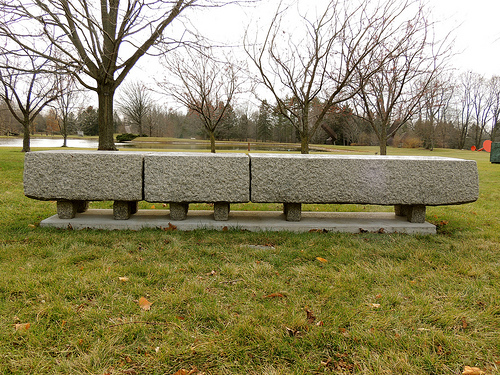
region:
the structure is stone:
[40, 142, 447, 194]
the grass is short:
[118, 296, 210, 370]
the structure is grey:
[287, 168, 346, 196]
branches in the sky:
[221, 28, 291, 70]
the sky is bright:
[197, 14, 234, 31]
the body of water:
[55, 135, 90, 150]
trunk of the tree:
[282, 89, 309, 152]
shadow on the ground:
[320, 207, 363, 220]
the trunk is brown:
[102, 100, 109, 130]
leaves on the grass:
[117, 280, 148, 322]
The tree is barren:
[46, 73, 83, 148]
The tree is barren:
[3, 52, 54, 147]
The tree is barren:
[51, 5, 140, 148]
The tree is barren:
[118, 83, 158, 139]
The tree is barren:
[153, 47, 239, 154]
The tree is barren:
[246, 22, 334, 152]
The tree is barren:
[346, 47, 422, 153]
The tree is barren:
[406, 78, 449, 149]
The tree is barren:
[446, 83, 480, 153]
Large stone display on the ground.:
[16, 140, 486, 230]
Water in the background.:
[0, 130, 327, 157]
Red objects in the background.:
[465, 133, 494, 158]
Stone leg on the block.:
[279, 201, 306, 222]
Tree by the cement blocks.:
[2, 0, 199, 155]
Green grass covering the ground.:
[2, 145, 499, 371]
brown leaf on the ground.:
[133, 292, 158, 314]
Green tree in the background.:
[77, 105, 103, 138]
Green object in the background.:
[486, 118, 498, 169]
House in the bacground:
[110, 102, 137, 138]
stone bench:
[17, 137, 489, 252]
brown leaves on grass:
[123, 267, 338, 347]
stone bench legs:
[48, 197, 428, 239]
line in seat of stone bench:
[128, 150, 160, 204]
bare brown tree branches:
[3, 3, 73, 80]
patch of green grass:
[43, 248, 89, 278]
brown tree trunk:
[88, 96, 128, 151]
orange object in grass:
[464, 131, 493, 154]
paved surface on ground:
[6, 130, 125, 152]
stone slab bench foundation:
[32, 205, 447, 243]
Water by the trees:
[2, 134, 122, 149]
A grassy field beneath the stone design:
[2, 145, 496, 374]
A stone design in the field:
[23, 151, 476, 236]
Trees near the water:
[0, 2, 496, 151]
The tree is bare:
[243, 1, 403, 155]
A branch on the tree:
[116, 0, 183, 87]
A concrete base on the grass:
[43, 211, 435, 230]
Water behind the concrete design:
[1, 137, 324, 154]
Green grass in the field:
[0, 147, 498, 373]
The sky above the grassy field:
[0, 0, 499, 111]